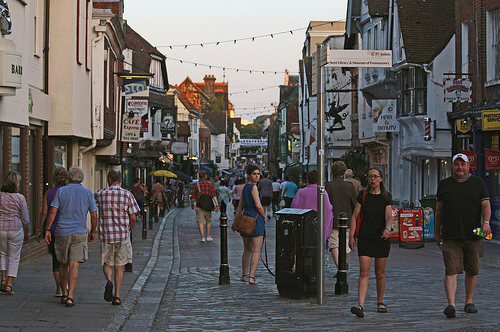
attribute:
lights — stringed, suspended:
[122, 24, 349, 117]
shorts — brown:
[410, 234, 499, 278]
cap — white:
[452, 152, 470, 161]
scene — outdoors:
[5, 5, 485, 329]